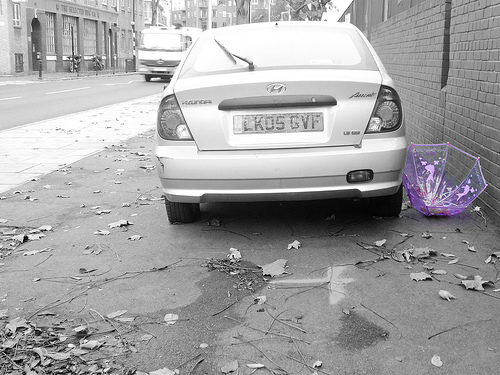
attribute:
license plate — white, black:
[232, 112, 324, 135]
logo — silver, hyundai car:
[181, 99, 212, 107]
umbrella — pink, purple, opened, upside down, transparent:
[401, 141, 488, 218]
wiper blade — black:
[212, 37, 255, 70]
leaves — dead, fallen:
[0, 130, 498, 374]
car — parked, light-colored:
[153, 20, 407, 224]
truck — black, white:
[136, 26, 198, 82]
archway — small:
[30, 16, 43, 70]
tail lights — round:
[157, 85, 403, 140]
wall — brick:
[368, 0, 499, 224]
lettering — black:
[342, 130, 360, 137]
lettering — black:
[54, 3, 100, 19]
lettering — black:
[349, 91, 377, 99]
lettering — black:
[181, 99, 212, 106]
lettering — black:
[232, 110, 324, 136]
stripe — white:
[1, 79, 141, 102]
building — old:
[1, 0, 168, 79]